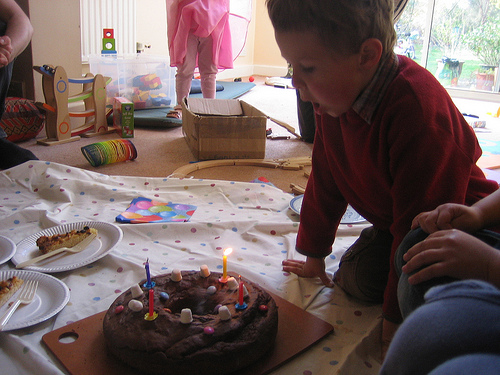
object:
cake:
[102, 271, 278, 375]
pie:
[36, 226, 97, 254]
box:
[181, 98, 267, 161]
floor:
[19, 75, 498, 192]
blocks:
[101, 28, 118, 59]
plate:
[41, 271, 335, 375]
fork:
[16, 233, 96, 268]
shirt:
[295, 54, 499, 324]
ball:
[249, 77, 255, 82]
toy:
[81, 139, 138, 167]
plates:
[0, 219, 124, 331]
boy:
[266, 0, 500, 300]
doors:
[389, 0, 498, 103]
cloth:
[0, 160, 386, 375]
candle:
[149, 289, 154, 317]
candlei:
[145, 258, 151, 285]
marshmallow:
[181, 308, 194, 324]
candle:
[223, 255, 227, 281]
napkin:
[115, 197, 197, 224]